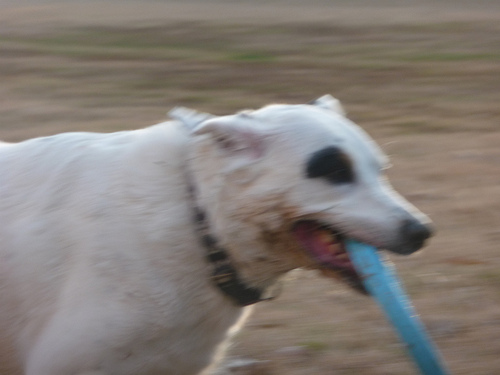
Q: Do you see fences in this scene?
A: No, there are no fences.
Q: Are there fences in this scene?
A: No, there are no fences.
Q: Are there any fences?
A: No, there are no fences.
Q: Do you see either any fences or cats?
A: No, there are no fences or cats.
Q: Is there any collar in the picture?
A: Yes, there is a collar.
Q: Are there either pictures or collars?
A: Yes, there is a collar.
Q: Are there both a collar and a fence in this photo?
A: No, there is a collar but no fences.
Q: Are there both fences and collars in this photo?
A: No, there is a collar but no fences.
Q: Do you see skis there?
A: No, there are no skis.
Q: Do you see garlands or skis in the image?
A: No, there are no skis or garlands.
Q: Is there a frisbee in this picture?
A: Yes, there is a frisbee.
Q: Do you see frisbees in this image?
A: Yes, there is a frisbee.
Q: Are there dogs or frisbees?
A: Yes, there is a frisbee.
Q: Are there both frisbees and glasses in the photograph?
A: No, there is a frisbee but no glasses.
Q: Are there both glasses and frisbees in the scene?
A: No, there is a frisbee but no glasses.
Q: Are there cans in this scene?
A: No, there are no cans.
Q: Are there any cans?
A: No, there are no cans.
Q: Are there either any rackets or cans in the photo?
A: No, there are no cans or rackets.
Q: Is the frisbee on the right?
A: Yes, the frisbee is on the right of the image.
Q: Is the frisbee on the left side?
A: No, the frisbee is on the right of the image.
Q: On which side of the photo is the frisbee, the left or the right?
A: The frisbee is on the right of the image.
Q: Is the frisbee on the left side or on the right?
A: The frisbee is on the right of the image.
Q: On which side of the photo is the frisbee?
A: The frisbee is on the right of the image.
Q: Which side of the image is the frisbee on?
A: The frisbee is on the right of the image.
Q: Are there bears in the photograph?
A: No, there are no bears.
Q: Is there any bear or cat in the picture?
A: No, there are no bears or cats.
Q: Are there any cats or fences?
A: No, there are no fences or cats.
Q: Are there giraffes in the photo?
A: No, there are no giraffes.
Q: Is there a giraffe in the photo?
A: No, there are no giraffes.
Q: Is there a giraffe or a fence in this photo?
A: No, there are no giraffes or fences.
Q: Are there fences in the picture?
A: No, there are no fences.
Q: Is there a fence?
A: No, there are no fences.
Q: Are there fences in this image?
A: No, there are no fences.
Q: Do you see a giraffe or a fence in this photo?
A: No, there are no fences or giraffes.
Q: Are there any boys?
A: No, there are no boys.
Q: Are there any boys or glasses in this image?
A: No, there are no boys or glasses.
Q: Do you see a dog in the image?
A: Yes, there is a dog.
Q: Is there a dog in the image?
A: Yes, there is a dog.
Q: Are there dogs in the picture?
A: Yes, there is a dog.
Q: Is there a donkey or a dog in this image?
A: Yes, there is a dog.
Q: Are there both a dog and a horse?
A: No, there is a dog but no horses.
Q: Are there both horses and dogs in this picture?
A: No, there is a dog but no horses.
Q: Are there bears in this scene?
A: No, there are no bears.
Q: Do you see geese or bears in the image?
A: No, there are no bears or geese.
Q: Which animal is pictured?
A: The animal is a dog.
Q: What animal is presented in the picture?
A: The animal is a dog.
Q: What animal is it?
A: The animal is a dog.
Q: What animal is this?
A: This is a dog.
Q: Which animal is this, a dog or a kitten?
A: This is a dog.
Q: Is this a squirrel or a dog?
A: This is a dog.